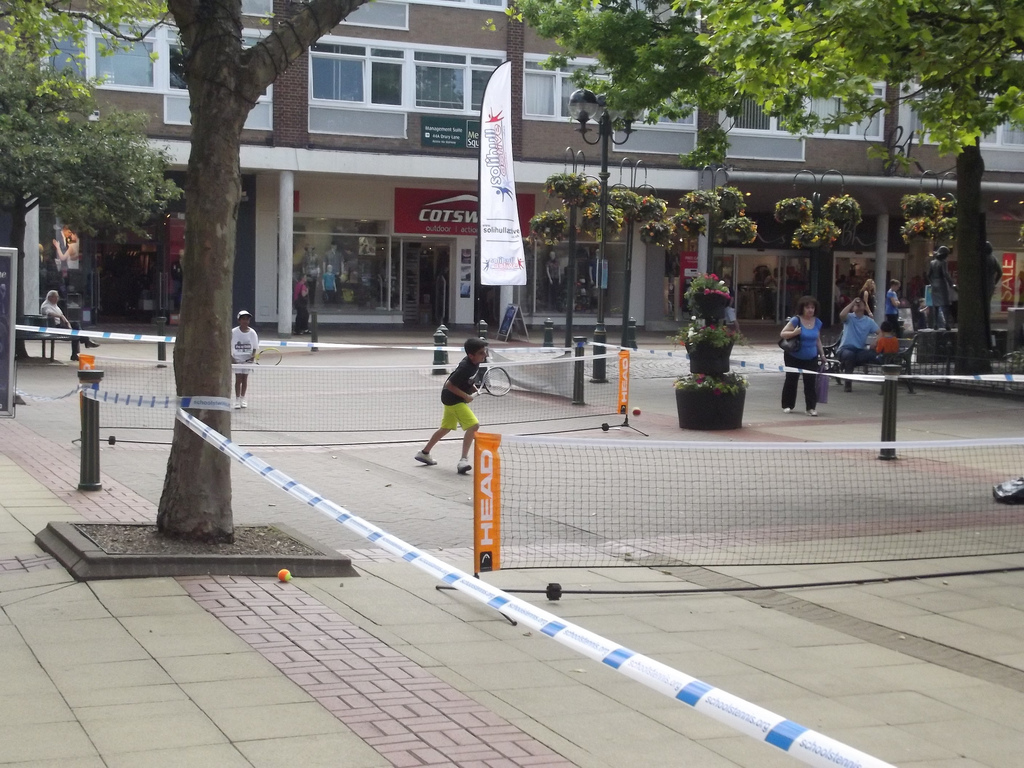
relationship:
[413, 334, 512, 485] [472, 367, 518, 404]
boy has a racket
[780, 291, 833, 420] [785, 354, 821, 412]
woman has pants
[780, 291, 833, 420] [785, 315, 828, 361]
woman has a shirt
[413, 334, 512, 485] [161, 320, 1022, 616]
boy plays tennis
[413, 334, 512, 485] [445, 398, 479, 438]
boy has shorts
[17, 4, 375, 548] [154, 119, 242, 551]
tree has trunk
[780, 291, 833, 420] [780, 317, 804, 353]
woman has a purse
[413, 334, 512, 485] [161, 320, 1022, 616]
boy playing tennis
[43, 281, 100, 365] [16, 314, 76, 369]
woman on a bench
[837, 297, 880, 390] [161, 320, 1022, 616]
man watching tennis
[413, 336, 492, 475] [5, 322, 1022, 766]
boy on street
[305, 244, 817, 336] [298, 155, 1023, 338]
people in a store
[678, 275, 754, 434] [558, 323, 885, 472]
flowers in middle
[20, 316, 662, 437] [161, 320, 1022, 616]
net for tennis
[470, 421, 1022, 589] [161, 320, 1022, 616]
net for tennis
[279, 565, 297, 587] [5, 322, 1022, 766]
ball on ground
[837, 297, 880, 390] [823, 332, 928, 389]
man on a bench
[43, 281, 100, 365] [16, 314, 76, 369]
man on a bench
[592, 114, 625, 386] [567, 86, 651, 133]
post has lamp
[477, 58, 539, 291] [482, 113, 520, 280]
banner has words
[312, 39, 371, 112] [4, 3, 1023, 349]
window above shop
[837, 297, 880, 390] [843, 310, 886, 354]
man has a shirt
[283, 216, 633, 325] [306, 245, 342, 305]
window has a mannequin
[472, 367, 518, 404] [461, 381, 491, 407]
racket in hand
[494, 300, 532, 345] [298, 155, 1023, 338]
board outside of store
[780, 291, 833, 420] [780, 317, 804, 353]
lady has a purse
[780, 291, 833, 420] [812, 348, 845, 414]
lady has a bag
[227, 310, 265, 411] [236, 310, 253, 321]
someone has a cap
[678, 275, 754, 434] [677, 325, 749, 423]
plants in pot